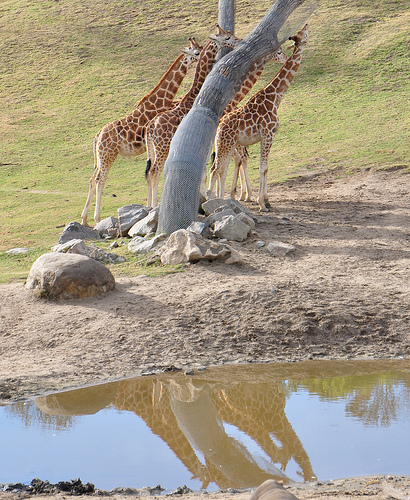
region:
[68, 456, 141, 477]
clear clean blue water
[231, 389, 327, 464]
long brown giraffe shadows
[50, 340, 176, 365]
a grey hard surface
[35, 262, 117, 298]
a big hard rock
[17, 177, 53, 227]
green patch of grass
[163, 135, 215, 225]
a long tree trunk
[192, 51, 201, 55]
a black giraffe eye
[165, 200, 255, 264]
a pile of rocks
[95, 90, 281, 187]
four identical baby giraffes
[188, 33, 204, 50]
two short giraffe ears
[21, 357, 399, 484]
water is murky and reflective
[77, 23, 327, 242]
group of four giraffes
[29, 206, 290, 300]
ring of grey rocks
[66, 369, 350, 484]
reflection of four giraffes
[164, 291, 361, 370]
sandy beach with giraffe footprints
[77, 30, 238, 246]
two giraffes eating leaves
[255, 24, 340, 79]
two giraffes eating leaves up high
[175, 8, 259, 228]
slanted tree trunk with missing bark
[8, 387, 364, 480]
watering hole for giraffes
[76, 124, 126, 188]
rear end of a giraffe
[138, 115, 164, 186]
giraffe tail with a black bushy end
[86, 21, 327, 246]
herd of yellow and brown giraffe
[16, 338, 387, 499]
The giraffe's reflection can be seen in the water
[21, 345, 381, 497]
The water is murky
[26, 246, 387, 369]
Sand surrounds the watering hole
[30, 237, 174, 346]
A large rock is in the sand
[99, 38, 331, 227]
Four giraffes stand under a tree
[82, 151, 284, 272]
The tree is surrounded by rocks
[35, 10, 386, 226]
The hillside is green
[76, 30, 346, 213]
The giraffes are all facing one way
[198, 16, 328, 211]
The giraffe looks upwards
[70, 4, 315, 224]
The giraffes stand between two trees